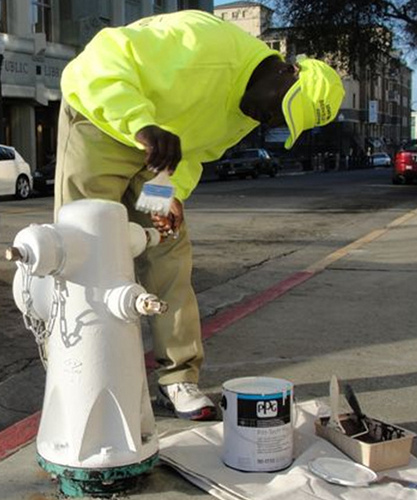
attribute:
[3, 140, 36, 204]
car — white, old, parked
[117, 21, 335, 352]
man — painting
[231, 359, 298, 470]
can — paint, white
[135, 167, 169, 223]
paint brush — white, without paint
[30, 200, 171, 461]
fire hydrand — tall, white, painted, green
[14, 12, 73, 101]
building — brown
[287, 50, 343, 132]
hat — yellow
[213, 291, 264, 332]
curb — red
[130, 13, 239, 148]
jacket — yellow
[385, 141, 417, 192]
car — red